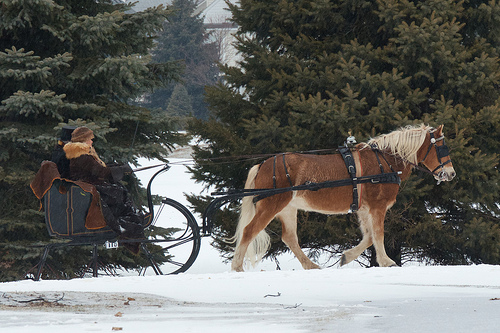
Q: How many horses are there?
A: 1.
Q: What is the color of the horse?
A: Brown.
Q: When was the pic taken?
A: During the day.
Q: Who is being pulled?
A: Two people.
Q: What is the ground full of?
A: Snow.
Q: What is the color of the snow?
A: White.